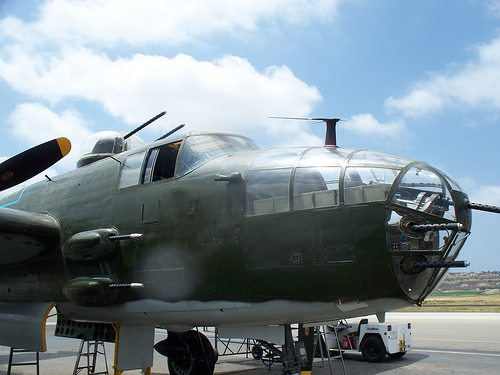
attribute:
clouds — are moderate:
[18, 2, 345, 49]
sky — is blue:
[2, 4, 499, 174]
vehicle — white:
[79, 139, 476, 356]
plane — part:
[15, 113, 472, 361]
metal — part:
[183, 230, 224, 256]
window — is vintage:
[110, 135, 199, 197]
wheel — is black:
[159, 328, 227, 373]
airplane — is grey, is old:
[0, 88, 490, 363]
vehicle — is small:
[309, 314, 419, 366]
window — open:
[143, 143, 180, 180]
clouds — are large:
[29, 28, 208, 128]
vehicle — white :
[332, 318, 415, 360]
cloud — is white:
[1, 0, 336, 158]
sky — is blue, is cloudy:
[4, 2, 499, 274]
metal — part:
[421, 249, 473, 272]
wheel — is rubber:
[156, 328, 226, 365]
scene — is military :
[2, 86, 492, 368]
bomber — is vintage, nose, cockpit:
[33, 111, 469, 372]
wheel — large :
[156, 330, 221, 373]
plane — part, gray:
[0, 111, 499, 373]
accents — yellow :
[36, 130, 135, 372]